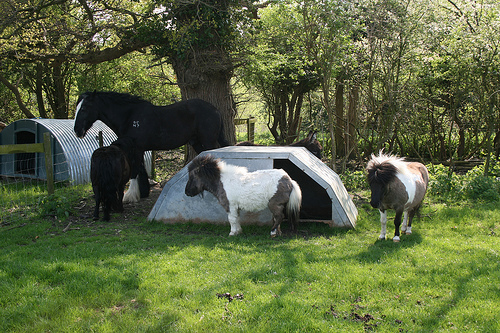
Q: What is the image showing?
A: It is showing a field.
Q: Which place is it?
A: It is a field.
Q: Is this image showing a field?
A: Yes, it is showing a field.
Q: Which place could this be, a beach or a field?
A: It is a field.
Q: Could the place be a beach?
A: No, it is a field.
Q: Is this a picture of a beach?
A: No, the picture is showing a field.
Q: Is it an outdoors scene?
A: Yes, it is outdoors.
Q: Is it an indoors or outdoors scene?
A: It is outdoors.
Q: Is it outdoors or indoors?
A: It is outdoors.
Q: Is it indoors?
A: No, it is outdoors.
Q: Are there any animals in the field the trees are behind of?
A: Yes, there is an animal in the field.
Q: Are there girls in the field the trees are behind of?
A: No, there is an animal in the field.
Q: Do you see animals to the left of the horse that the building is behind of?
A: Yes, there is an animal to the left of the horse.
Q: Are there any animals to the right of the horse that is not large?
A: No, the animal is to the left of the horse.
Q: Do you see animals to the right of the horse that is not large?
A: No, the animal is to the left of the horse.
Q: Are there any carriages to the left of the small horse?
A: No, there is an animal to the left of the horse.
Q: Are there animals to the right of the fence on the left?
A: Yes, there is an animal to the right of the fence.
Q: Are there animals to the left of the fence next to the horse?
A: No, the animal is to the right of the fence.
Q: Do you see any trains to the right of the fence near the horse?
A: No, there is an animal to the right of the fence.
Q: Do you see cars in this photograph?
A: No, there are no cars.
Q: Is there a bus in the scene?
A: No, there are no buses.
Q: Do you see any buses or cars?
A: No, there are no buses or cars.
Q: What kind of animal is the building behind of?
A: The building is behind the horse.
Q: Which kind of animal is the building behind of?
A: The building is behind the horse.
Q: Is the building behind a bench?
A: No, the building is behind the horse.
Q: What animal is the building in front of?
A: The building is in front of the horse.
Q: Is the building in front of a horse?
A: Yes, the building is in front of a horse.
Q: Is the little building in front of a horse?
A: Yes, the building is in front of a horse.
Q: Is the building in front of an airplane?
A: No, the building is in front of a horse.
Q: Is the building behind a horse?
A: No, the building is in front of a horse.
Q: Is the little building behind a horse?
A: No, the building is in front of a horse.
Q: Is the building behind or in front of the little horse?
A: The building is in front of the horse.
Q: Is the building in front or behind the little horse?
A: The building is in front of the horse.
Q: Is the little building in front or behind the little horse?
A: The building is in front of the horse.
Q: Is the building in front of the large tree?
A: Yes, the building is in front of the tree.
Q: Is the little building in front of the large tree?
A: Yes, the building is in front of the tree.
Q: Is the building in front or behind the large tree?
A: The building is in front of the tree.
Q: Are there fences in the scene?
A: Yes, there is a fence.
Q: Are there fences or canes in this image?
A: Yes, there is a fence.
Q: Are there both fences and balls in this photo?
A: No, there is a fence but no balls.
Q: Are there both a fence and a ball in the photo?
A: No, there is a fence but no balls.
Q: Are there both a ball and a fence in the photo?
A: No, there is a fence but no balls.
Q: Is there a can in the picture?
A: No, there are no cans.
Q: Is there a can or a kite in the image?
A: No, there are no cans or kites.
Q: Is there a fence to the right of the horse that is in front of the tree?
A: Yes, there is a fence to the right of the horse.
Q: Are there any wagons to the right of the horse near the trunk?
A: No, there is a fence to the right of the horse.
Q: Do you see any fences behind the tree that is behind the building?
A: Yes, there is a fence behind the tree.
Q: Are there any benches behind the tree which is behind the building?
A: No, there is a fence behind the tree.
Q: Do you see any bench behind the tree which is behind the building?
A: No, there is a fence behind the tree.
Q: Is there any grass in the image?
A: Yes, there is grass.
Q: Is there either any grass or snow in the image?
A: Yes, there is grass.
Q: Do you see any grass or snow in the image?
A: Yes, there is grass.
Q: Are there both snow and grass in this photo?
A: No, there is grass but no snow.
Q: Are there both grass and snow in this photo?
A: No, there is grass but no snow.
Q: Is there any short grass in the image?
A: Yes, there is short grass.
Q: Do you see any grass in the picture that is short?
A: Yes, there is grass that is short.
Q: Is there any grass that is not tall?
A: Yes, there is short grass.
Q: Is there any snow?
A: No, there is no snow.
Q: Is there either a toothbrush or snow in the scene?
A: No, there are no snow or toothbrushes.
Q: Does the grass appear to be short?
A: Yes, the grass is short.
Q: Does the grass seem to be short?
A: Yes, the grass is short.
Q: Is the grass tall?
A: No, the grass is short.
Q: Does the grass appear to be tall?
A: No, the grass is short.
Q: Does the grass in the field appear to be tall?
A: No, the grass is short.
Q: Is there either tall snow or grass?
A: No, there is grass but it is short.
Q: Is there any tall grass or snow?
A: No, there is grass but it is short.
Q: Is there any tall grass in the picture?
A: No, there is grass but it is short.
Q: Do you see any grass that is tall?
A: No, there is grass but it is short.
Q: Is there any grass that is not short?
A: No, there is grass but it is short.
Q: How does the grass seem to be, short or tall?
A: The grass is short.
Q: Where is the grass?
A: The grass is in the field.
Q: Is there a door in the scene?
A: Yes, there is a door.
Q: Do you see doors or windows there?
A: Yes, there is a door.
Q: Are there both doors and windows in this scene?
A: No, there is a door but no windows.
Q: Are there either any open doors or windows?
A: Yes, there is an open door.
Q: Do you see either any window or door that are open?
A: Yes, the door is open.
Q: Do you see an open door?
A: Yes, there is an open door.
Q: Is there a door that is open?
A: Yes, there is a door that is open.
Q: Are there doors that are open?
A: Yes, there is a door that is open.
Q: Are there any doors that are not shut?
A: Yes, there is a open door.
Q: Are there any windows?
A: No, there are no windows.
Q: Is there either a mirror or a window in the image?
A: No, there are no windows or mirrors.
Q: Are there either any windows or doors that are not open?
A: No, there is a door but it is open.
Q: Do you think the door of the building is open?
A: Yes, the door is open.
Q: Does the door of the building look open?
A: Yes, the door is open.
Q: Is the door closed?
A: No, the door is open.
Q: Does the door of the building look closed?
A: No, the door is open.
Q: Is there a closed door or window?
A: No, there is a door but it is open.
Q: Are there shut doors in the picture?
A: No, there is a door but it is open.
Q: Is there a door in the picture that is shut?
A: No, there is a door but it is open.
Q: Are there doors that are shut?
A: No, there is a door but it is open.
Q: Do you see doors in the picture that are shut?
A: No, there is a door but it is open.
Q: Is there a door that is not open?
A: No, there is a door but it is open.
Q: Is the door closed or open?
A: The door is open.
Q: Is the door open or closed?
A: The door is open.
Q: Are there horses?
A: Yes, there is a horse.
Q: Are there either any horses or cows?
A: Yes, there is a horse.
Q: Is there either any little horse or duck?
A: Yes, there is a little horse.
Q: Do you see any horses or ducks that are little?
A: Yes, the horse is little.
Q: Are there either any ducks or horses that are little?
A: Yes, the horse is little.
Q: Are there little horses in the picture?
A: Yes, there is a little horse.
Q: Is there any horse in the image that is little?
A: Yes, there is a horse that is little.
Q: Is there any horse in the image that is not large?
A: Yes, there is a little horse.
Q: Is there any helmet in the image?
A: No, there are no helmets.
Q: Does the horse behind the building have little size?
A: Yes, the horse is little.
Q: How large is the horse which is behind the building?
A: The horse is little.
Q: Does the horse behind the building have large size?
A: No, the horse is little.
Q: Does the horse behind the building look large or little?
A: The horse is little.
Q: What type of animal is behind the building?
A: The animal is a horse.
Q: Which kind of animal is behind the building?
A: The animal is a horse.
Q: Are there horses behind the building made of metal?
A: Yes, there is a horse behind the building.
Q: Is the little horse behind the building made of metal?
A: Yes, the horse is behind the building.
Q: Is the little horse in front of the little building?
A: No, the horse is behind the building.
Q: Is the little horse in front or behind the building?
A: The horse is behind the building.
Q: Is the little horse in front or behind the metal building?
A: The horse is behind the building.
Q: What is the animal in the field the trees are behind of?
A: The animal is a horse.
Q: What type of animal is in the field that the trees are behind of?
A: The animal is a horse.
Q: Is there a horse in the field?
A: Yes, there is a horse in the field.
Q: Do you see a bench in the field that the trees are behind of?
A: No, there is a horse in the field.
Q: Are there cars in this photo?
A: No, there are no cars.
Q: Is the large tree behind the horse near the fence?
A: Yes, the tree is behind the horse.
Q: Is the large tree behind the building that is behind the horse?
A: Yes, the tree is behind the building.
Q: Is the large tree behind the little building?
A: Yes, the tree is behind the building.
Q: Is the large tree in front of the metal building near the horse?
A: No, the tree is behind the building.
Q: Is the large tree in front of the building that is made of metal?
A: No, the tree is behind the building.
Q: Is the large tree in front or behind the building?
A: The tree is behind the building.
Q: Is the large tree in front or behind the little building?
A: The tree is behind the building.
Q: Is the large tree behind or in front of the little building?
A: The tree is behind the building.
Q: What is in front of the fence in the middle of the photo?
A: The tree is in front of the fence.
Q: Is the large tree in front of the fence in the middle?
A: Yes, the tree is in front of the fence.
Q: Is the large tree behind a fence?
A: No, the tree is in front of a fence.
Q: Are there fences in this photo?
A: Yes, there is a fence.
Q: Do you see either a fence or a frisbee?
A: Yes, there is a fence.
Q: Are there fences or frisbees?
A: Yes, there is a fence.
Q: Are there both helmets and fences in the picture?
A: No, there is a fence but no helmets.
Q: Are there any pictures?
A: No, there are no pictures.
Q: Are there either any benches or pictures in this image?
A: No, there are no pictures or benches.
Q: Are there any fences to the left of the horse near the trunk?
A: Yes, there is a fence to the left of the horse.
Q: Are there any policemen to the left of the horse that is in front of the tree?
A: No, there is a fence to the left of the horse.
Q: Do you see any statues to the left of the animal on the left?
A: No, there is a fence to the left of the animal.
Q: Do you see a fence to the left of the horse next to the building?
A: Yes, there is a fence to the left of the horse.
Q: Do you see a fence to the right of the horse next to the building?
A: No, the fence is to the left of the horse.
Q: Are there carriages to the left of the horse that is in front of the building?
A: No, there is a fence to the left of the horse.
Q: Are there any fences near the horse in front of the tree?
A: Yes, there is a fence near the horse.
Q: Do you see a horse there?
A: Yes, there is a horse.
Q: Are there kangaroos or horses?
A: Yes, there is a horse.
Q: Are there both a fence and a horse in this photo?
A: Yes, there are both a horse and a fence.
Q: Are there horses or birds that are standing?
A: Yes, the horse is standing.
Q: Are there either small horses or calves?
A: Yes, there is a small horse.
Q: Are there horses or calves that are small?
A: Yes, the horse is small.